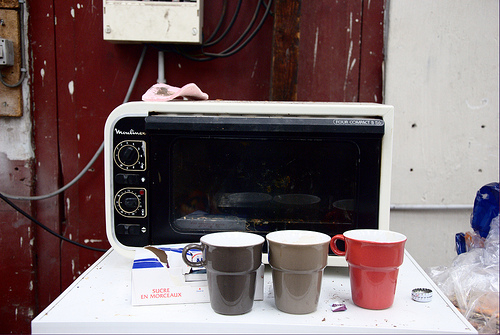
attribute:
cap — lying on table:
[411, 286, 433, 302]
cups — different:
[327, 228, 409, 310]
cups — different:
[263, 228, 330, 312]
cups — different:
[178, 231, 265, 315]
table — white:
[27, 242, 480, 328]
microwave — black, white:
[103, 99, 391, 254]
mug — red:
[325, 223, 408, 314]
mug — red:
[323, 227, 425, 309]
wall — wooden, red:
[0, 4, 388, 254]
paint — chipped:
[336, 10, 366, 75]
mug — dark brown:
[178, 226, 268, 323]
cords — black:
[171, 0, 274, 62]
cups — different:
[182, 228, 406, 317]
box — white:
[128, 239, 266, 308]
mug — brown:
[182, 226, 266, 319]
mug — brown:
[264, 225, 333, 314]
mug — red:
[330, 225, 407, 313]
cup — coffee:
[180, 220, 267, 316]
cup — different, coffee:
[330, 225, 411, 312]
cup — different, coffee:
[179, 226, 264, 315]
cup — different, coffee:
[262, 224, 329, 314]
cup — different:
[263, 227, 334, 315]